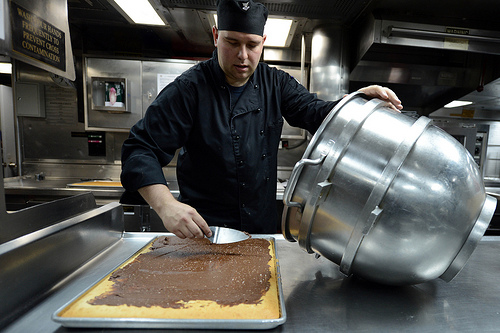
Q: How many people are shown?
A: 1.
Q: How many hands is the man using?
A: 2.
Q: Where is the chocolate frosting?
A: On cake.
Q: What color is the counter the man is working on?
A: Silver.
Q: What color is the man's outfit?
A: Black.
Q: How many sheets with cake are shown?
A: 2.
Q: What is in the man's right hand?
A: Spatula.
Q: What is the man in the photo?
A: Chef.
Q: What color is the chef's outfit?
A: Black.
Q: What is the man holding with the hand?
A: Large silver pots.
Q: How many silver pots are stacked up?
A: Three.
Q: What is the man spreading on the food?
A: Icing.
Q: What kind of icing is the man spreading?
A: Chocolate.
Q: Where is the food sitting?
A: Long silver pan.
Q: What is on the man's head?
A: Chef's hat.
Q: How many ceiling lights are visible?
A: Three.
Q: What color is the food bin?
A: Silver.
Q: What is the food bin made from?
A: Metal.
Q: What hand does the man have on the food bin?
A: Left.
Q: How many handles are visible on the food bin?
A: One.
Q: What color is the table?
A: Silver.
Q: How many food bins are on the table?
A: One.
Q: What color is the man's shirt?
A: Black.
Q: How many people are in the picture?
A: One.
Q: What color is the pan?
A: Silver.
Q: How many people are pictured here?
A: One.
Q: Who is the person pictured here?
A: The chef.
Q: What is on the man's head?
A: A hat.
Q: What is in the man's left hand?
A: A mixing bowl.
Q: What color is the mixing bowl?
A: Silver.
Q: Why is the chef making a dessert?
A: It's for the dinner party.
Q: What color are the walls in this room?
A: Silver.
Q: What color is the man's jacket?
A: Black.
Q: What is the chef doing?
A: Icing a cake.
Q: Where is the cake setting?
A: In the kitchen.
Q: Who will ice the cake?
A: The cook.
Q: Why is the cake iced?
A: Added flavor.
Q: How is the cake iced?
A: Spread with a spatula.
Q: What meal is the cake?
A: Dessert.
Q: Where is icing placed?
A: On top the cake.